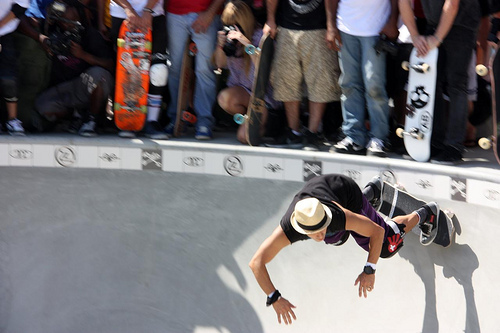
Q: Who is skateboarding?
A: A man.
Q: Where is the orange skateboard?
A: Being held on the sidelines.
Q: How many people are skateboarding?
A: One.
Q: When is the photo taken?
A: Daytime.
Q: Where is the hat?
A: On the skateboarder's head.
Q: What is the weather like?
A: Sunny.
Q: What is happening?
A: Spectators watch a skateboarder.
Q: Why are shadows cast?
A: It is sunny.